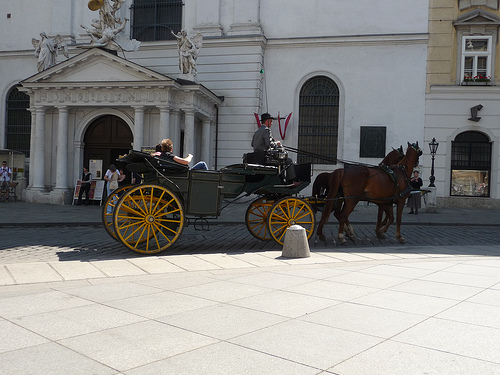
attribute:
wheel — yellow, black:
[115, 151, 195, 255]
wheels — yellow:
[97, 184, 210, 255]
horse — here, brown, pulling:
[318, 136, 424, 243]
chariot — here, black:
[81, 100, 437, 263]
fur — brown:
[356, 168, 384, 190]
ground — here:
[145, 253, 315, 370]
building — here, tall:
[40, 48, 218, 223]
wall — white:
[363, 35, 422, 128]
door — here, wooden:
[447, 87, 500, 207]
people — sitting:
[139, 130, 205, 175]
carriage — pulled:
[120, 153, 343, 227]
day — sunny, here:
[40, 26, 450, 349]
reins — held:
[290, 145, 352, 182]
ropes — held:
[299, 139, 371, 179]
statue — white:
[166, 26, 222, 99]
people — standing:
[69, 156, 95, 202]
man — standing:
[98, 160, 128, 205]